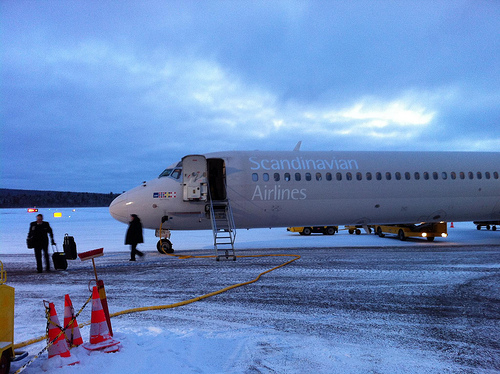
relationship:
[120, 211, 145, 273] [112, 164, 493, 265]
woman walking by airplane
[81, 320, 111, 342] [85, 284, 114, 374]
small white stripe on traffic cone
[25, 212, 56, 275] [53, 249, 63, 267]
man holding a suitcase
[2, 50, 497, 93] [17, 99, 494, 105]
thick grey clouds hanging in sky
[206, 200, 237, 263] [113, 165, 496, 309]
ladder by exit of plane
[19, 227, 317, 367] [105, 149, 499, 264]
cord running out to an plane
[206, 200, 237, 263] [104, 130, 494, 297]
ladder going up to an airplane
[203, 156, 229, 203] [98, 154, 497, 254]
door of an airplane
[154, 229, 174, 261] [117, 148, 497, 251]
nose wheel of an airplane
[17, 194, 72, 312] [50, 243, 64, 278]
man pulling a suitcase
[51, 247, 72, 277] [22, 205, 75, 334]
suitcase pulled by a man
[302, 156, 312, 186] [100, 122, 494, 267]
window on an airplane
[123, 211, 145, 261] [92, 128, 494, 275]
woman walking next to plane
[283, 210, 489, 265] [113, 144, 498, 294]
yellow trucks behind plane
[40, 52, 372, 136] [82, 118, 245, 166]
clouds in sky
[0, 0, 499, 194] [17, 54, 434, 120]
clouds in sky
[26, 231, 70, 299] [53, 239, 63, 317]
travelling bag being pulled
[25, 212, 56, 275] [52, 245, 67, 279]
man pulling a travelling bag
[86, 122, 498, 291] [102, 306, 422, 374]
plane on ground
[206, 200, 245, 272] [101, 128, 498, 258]
ladder into plane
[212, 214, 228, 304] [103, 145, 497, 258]
door of a plane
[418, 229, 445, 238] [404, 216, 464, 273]
lights of a truck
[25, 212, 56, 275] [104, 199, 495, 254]
man walking away from a jet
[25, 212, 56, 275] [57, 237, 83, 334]
man carrying a bag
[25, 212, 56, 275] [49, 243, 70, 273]
man pulling a suitcase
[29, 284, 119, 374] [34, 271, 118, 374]
yellow and orange hazard cones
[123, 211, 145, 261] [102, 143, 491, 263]
woman walking in front of a jet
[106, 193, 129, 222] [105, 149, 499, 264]
nose cone of plane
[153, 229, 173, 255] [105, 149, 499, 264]
landing gear of plane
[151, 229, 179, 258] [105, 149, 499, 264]
landing gear of plane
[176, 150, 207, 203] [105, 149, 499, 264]
passenger door on plane